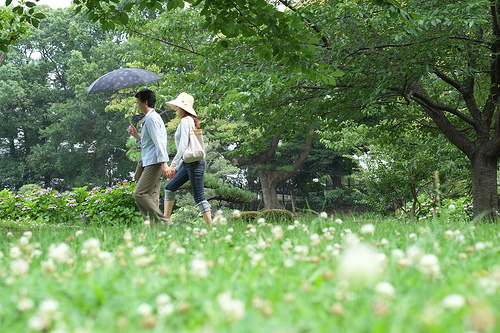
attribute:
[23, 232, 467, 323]
grass — green, tall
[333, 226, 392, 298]
flowers — white, puffy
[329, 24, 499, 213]
tree — thick, leafy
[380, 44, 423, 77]
leaves — green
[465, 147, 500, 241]
trunk — gray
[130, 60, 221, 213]
people — walking, young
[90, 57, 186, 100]
umbrella — black, open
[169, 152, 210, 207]
jeans — blue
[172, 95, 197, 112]
hat — straw, white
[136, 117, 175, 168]
jacket — white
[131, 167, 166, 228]
pants — brown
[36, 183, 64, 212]
flowers — purpule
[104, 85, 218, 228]
couple — young